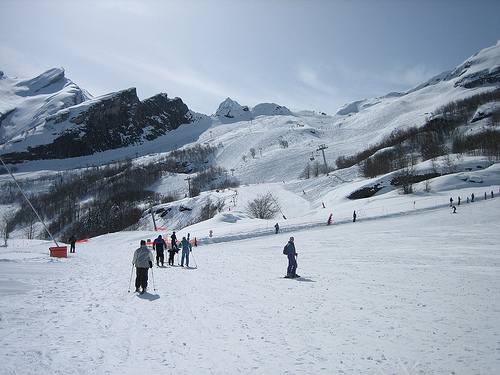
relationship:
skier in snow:
[131, 239, 156, 294] [225, 297, 498, 362]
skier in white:
[132, 237, 163, 304] [131, 254, 154, 269]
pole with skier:
[127, 255, 139, 295] [132, 237, 163, 304]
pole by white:
[127, 255, 139, 295] [131, 254, 154, 269]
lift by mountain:
[306, 144, 331, 175] [196, 90, 491, 197]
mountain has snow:
[196, 90, 491, 197] [225, 297, 498, 362]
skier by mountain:
[131, 239, 156, 294] [196, 90, 491, 197]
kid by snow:
[168, 244, 178, 264] [225, 297, 498, 362]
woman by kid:
[178, 234, 191, 269] [168, 244, 178, 264]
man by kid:
[155, 236, 165, 265] [168, 244, 178, 264]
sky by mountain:
[113, 17, 379, 73] [196, 90, 491, 197]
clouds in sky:
[85, 5, 226, 89] [113, 17, 379, 73]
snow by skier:
[225, 297, 498, 362] [131, 239, 156, 294]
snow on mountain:
[225, 297, 498, 362] [196, 90, 491, 197]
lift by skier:
[306, 144, 331, 175] [131, 239, 156, 294]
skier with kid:
[131, 239, 156, 294] [168, 244, 178, 264]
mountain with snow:
[196, 90, 491, 197] [225, 297, 498, 362]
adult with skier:
[281, 240, 299, 275] [132, 237, 163, 304]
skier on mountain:
[352, 207, 368, 233] [196, 90, 491, 197]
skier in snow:
[132, 237, 163, 304] [225, 297, 498, 362]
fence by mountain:
[74, 239, 89, 244] [196, 90, 491, 197]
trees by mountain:
[29, 177, 142, 218] [196, 90, 491, 197]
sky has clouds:
[113, 17, 379, 73] [85, 5, 226, 89]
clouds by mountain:
[85, 5, 226, 89] [196, 90, 491, 197]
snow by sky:
[225, 297, 498, 362] [113, 17, 379, 73]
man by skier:
[155, 236, 165, 265] [132, 237, 163, 304]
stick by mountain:
[319, 143, 332, 172] [196, 90, 491, 197]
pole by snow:
[127, 255, 139, 295] [225, 297, 498, 362]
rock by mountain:
[349, 186, 387, 207] [196, 90, 491, 197]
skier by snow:
[132, 237, 163, 304] [225, 297, 498, 362]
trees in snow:
[29, 177, 142, 218] [225, 297, 498, 362]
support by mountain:
[1, 156, 83, 260] [196, 90, 491, 197]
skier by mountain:
[132, 237, 163, 304] [196, 90, 491, 197]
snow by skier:
[225, 297, 498, 362] [132, 237, 163, 304]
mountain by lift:
[196, 90, 491, 197] [306, 144, 331, 175]